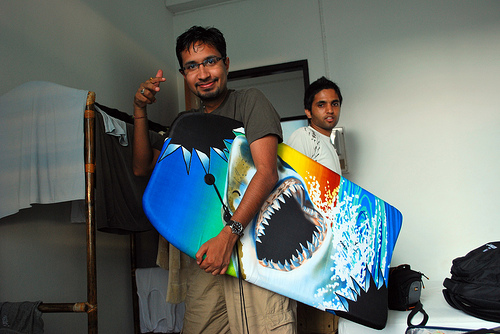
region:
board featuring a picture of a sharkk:
[141, 109, 401, 326]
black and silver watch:
[225, 219, 244, 236]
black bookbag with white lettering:
[444, 237, 499, 323]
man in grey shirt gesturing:
[131, 25, 296, 332]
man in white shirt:
[285, 74, 343, 177]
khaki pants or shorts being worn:
[177, 242, 294, 332]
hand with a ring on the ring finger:
[131, 70, 165, 115]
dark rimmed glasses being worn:
[180, 54, 226, 73]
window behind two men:
[182, 60, 314, 164]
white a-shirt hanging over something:
[133, 266, 193, 333]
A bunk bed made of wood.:
[1, 81, 158, 332]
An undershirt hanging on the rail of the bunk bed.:
[132, 258, 182, 330]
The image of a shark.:
[220, 125, 340, 300]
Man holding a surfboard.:
[125, 30, 395, 325]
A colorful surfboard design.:
[140, 110, 400, 320]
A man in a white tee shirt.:
[285, 71, 360, 171]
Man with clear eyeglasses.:
[168, 20, 248, 107]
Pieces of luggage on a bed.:
[393, 238, 498, 333]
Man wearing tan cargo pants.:
[181, 262, 306, 332]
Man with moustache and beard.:
[166, 14, 259, 109]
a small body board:
[143, 107, 414, 328]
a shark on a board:
[230, 156, 361, 292]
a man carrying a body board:
[136, 24, 416, 331]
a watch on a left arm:
[218, 218, 244, 239]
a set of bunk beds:
[1, 68, 155, 331]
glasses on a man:
[176, 57, 226, 72]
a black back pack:
[440, 236, 499, 318]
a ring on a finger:
[136, 88, 150, 98]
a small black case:
[384, 264, 426, 329]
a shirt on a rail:
[132, 268, 170, 329]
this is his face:
[178, 40, 230, 102]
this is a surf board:
[137, 107, 403, 317]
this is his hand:
[129, 64, 167, 109]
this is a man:
[287, 73, 346, 330]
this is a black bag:
[439, 238, 498, 333]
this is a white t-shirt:
[0, 80, 95, 220]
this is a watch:
[220, 218, 250, 237]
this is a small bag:
[377, 261, 429, 328]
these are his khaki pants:
[180, 256, 299, 332]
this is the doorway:
[179, 58, 316, 332]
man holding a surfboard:
[128, 27, 296, 332]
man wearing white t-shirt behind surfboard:
[284, 76, 344, 177]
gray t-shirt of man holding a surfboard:
[155, 85, 286, 149]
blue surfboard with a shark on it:
[142, 106, 402, 326]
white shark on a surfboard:
[221, 130, 336, 290]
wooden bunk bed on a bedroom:
[0, 75, 170, 325]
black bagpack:
[441, 240, 496, 320]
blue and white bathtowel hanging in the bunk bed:
[0, 75, 91, 220]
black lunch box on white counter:
[383, 261, 424, 315]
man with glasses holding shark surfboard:
[129, 23, 293, 332]